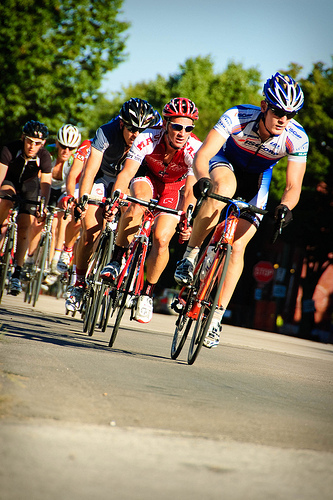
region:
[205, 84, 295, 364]
person is riding a bicycle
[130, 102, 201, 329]
person is riding a bicycle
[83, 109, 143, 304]
person is riding a bicycle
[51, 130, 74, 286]
person is riding a bicycle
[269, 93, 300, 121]
person is wearing sunglasses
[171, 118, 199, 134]
person is wearing sunglasses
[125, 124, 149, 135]
person is wearing sunglasses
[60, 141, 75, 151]
person is wearing sunglasses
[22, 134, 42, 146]
person is wearing sunglasses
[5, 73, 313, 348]
people riding bikes on the street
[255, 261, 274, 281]
a stop sign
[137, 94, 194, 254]
a person with a red helmet on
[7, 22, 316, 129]
the trees behind the bikes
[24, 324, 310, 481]
the street under the bikes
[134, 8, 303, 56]
the sky above the trees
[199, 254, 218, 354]
the wheel on the bike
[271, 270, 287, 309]
street signs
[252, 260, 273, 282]
blurry red stop sign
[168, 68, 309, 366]
a cyclist with a blue helmet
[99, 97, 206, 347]
a cyclist with a red helmet on his head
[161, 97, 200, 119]
a big red helmet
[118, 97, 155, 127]
a black regular sized helmet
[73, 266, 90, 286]
a red stocking with white inscriptions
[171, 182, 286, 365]
orange bicycle with black handles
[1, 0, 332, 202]
green huge big trees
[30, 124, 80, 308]
cyclist with opened up shirt and white helmet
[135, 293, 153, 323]
a wite laced sneaker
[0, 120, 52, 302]
a bike racer in a black shirt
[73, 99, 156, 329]
a bike racer in a black shirt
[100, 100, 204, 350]
a bike racer in a red shirt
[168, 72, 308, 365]
a bike racer in a blue and white shirt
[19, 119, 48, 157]
the bike racer's black safety helmet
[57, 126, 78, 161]
the bike racer's white safety helmet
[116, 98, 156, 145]
the bike racer's black safety helmet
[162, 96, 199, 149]
the bike racer's red safety helmet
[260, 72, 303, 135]
the bike racer's blue safety helmet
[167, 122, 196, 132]
white rimmed sun glasses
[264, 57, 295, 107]
blue and white helmet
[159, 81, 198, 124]
red and grey helmet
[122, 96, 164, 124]
black and white helmet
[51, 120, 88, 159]
man has white helmet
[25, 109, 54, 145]
man has black helmet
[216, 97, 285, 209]
blue and white outfit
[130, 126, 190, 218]
red and white outfit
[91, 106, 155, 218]
black and white outfit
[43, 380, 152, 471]
road is light grey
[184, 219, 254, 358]
orange and black bike